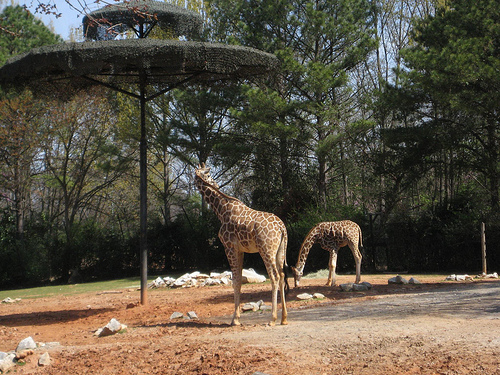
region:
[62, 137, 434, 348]
giraffes on flat ground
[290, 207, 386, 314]
giraffe with head touching ground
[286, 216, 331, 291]
curve of giraffe's neck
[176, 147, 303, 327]
giraffe with head turned to side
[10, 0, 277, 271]
elevated structure with two tiers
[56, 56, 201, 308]
blacks supports and pole under umbrella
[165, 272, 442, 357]
sets of double stones along a path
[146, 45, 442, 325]
tall trees in back of giraffes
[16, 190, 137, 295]
grass in front of trees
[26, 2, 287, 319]
giraffe under tall umbrella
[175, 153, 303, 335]
adult giraffe at a zoo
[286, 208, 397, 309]
young giraffe at zoo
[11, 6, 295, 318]
metal canopy built in zoo exhibit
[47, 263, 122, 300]
grass inside animal exhibit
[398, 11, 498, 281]
evergreen trees in zoo exhibit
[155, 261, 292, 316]
pile of rocks in zoo exhibit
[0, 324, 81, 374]
pile of rocks in zoo exhibit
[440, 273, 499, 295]
pile of rocks in zoo exhibit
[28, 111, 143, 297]
green trees and shrubs on edge of zoo exhibit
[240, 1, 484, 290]
green trees and shrubs on edge of zoo exhibit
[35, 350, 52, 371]
a small rock on the ground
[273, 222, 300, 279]
the tail of a giraffe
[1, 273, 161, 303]
a patch of green grass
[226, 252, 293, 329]
the legs of a giraffe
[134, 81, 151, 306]
a black metal pole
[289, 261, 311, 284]
the head of a giraffe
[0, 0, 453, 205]
a clear blue sky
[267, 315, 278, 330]
the hoof of a giraffe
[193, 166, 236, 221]
the neck of a girfaffe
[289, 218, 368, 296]
a giraffe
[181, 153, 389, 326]
There are two giraffes in the photo.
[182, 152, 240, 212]
The giraffe is looking at the other.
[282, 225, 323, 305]
The giraffe has it's head down.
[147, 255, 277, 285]
Pile of rocks on the ground.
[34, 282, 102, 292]
The grass is green.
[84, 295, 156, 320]
The ground is brown.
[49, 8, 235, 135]
A black umbrella on a pole.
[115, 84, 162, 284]
The pole is black.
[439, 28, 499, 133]
The tree leaves are green.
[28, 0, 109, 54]
The sky is blue.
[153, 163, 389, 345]
Two girraffes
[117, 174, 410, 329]
Two girraffes standing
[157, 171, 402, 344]
One girraffe looking, one girraffe eating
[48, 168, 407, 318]
Two girrafes standing with trees behind them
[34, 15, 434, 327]
Two girraffes standing near a tall tree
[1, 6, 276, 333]
man-made object all by itself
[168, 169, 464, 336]
Two girraffes by themselves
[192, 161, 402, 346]
Two giraffes standing on dirt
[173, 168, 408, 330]
Two giraffes not interacting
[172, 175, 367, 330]
Two giraffes ignoring each other